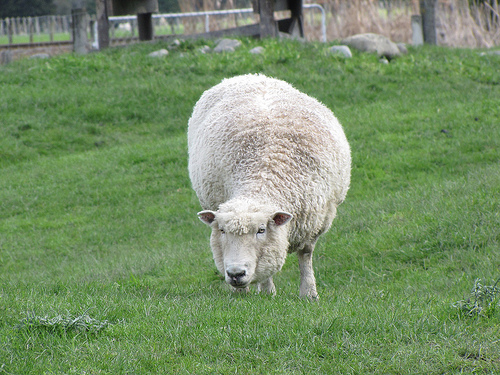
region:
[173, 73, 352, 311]
white sheep eating grass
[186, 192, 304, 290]
white sheep's head and ears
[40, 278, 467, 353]
green grass in pasture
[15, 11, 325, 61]
dark brown fence in background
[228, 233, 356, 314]
white sheep's front legs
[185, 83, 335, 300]
fluffy woolly white sheep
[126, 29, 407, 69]
grey rocks in field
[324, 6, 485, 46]
tan tall hay in back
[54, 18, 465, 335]
white sheep eating grass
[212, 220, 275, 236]
eyes of white sheep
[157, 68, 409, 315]
sheep in the grass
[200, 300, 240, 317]
patch of green grass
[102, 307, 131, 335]
patch of green grass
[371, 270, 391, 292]
patch of green grass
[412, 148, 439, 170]
patch of green grass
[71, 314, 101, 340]
patch of green grass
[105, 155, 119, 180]
patch of green grass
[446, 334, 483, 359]
patch of green grass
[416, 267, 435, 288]
patch of green grass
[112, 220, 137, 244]
patch of green grass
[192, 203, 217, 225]
The left ear of the sheep.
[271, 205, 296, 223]
The right ear of the sheep.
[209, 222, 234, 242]
The left eye of the sheep.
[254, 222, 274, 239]
The right eye of the sheep.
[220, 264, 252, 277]
The nose of the sheep.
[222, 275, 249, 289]
The mouth area of the sheep.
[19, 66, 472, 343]
The grass area the sheep is standing in.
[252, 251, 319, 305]
The front legs of the sheep.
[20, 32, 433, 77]
The rocks behind the sheep.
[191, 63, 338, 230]
The round body of the sheep.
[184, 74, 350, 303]
a sheep in a field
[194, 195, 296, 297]
the head of a sheep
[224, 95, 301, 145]
the wool of a sheep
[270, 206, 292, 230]
the ear of a sheep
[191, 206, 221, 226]
the ear of a sheep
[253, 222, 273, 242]
the eye of a sheep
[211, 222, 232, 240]
the eye of a sheep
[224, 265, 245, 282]
the nose of a sheep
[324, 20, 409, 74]
a couple rocks in a field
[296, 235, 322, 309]
the front leg of a sheep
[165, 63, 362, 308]
sheep in a field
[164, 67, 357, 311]
sheep eating grass in a field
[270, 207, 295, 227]
ear of a sheep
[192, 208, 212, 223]
ear of a sheep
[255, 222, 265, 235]
eye of a sheep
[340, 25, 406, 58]
boulder in the grass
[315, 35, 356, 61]
boulder in the grass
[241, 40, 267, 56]
boulder in the grass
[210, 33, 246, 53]
boulder in the grass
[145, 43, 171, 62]
boulder in the grass